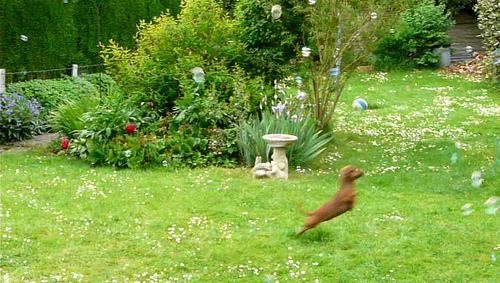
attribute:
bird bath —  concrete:
[250, 134, 297, 181]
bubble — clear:
[268, 2, 283, 21]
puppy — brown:
[292, 160, 369, 238]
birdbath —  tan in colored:
[248, 125, 301, 185]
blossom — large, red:
[122, 122, 135, 134]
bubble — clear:
[270, 2, 282, 17]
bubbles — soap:
[434, 167, 498, 222]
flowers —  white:
[464, 170, 496, 214]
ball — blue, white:
[346, 82, 375, 136]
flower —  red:
[119, 117, 136, 139]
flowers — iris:
[227, 75, 346, 155]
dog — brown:
[295, 161, 364, 240]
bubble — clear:
[189, 67, 207, 85]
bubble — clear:
[346, 94, 373, 114]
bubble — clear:
[261, 2, 284, 19]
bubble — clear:
[480, 190, 499, 221]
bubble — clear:
[365, 9, 381, 21]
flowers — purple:
[7, 83, 41, 137]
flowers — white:
[42, 165, 191, 258]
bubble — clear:
[482, 194, 498, 210]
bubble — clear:
[457, 200, 475, 216]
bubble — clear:
[470, 171, 484, 185]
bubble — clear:
[465, 42, 473, 56]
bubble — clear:
[388, 28, 395, 33]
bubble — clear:
[369, 11, 376, 18]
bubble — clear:
[327, 68, 337, 77]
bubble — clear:
[300, 48, 310, 57]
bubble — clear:
[193, 68, 206, 81]